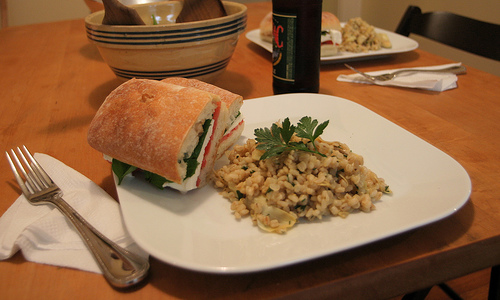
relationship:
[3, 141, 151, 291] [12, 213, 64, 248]
fork on napkin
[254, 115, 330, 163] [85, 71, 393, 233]
cilantro on food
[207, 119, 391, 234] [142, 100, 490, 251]
rice on plate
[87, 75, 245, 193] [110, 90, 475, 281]
sandwich on plate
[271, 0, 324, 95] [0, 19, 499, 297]
beer bottle on table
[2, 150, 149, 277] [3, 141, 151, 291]
napkin under in fork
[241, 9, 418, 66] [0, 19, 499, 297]
plate on table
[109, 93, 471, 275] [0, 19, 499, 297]
dish on table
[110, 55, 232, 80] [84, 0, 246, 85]
black stripes on bowl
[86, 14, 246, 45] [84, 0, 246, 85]
black stripes on bowl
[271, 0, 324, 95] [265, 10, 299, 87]
beer bottle has a label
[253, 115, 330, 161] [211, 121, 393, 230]
cilantro on eggs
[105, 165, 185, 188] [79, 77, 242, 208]
spinach on sandwich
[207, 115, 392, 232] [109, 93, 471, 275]
scrambled eggs is on dish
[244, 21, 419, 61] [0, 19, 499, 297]
plate is on table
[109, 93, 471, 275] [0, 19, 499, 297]
dish is on table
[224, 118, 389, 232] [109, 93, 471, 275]
rice is on dish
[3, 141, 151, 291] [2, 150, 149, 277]
fork is on napkin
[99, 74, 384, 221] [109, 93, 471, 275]
lunch is on dish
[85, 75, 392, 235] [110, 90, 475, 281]
lunch is on plate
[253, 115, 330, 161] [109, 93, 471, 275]
cilantro is on dish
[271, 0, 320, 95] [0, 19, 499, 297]
beer bottle is on table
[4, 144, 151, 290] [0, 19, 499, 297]
fork is on table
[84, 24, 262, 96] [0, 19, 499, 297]
bowl is on table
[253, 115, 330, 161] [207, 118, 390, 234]
cilantro is on rice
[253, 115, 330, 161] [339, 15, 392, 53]
cilantro is on rice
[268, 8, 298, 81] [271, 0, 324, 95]
label is on beer bottle